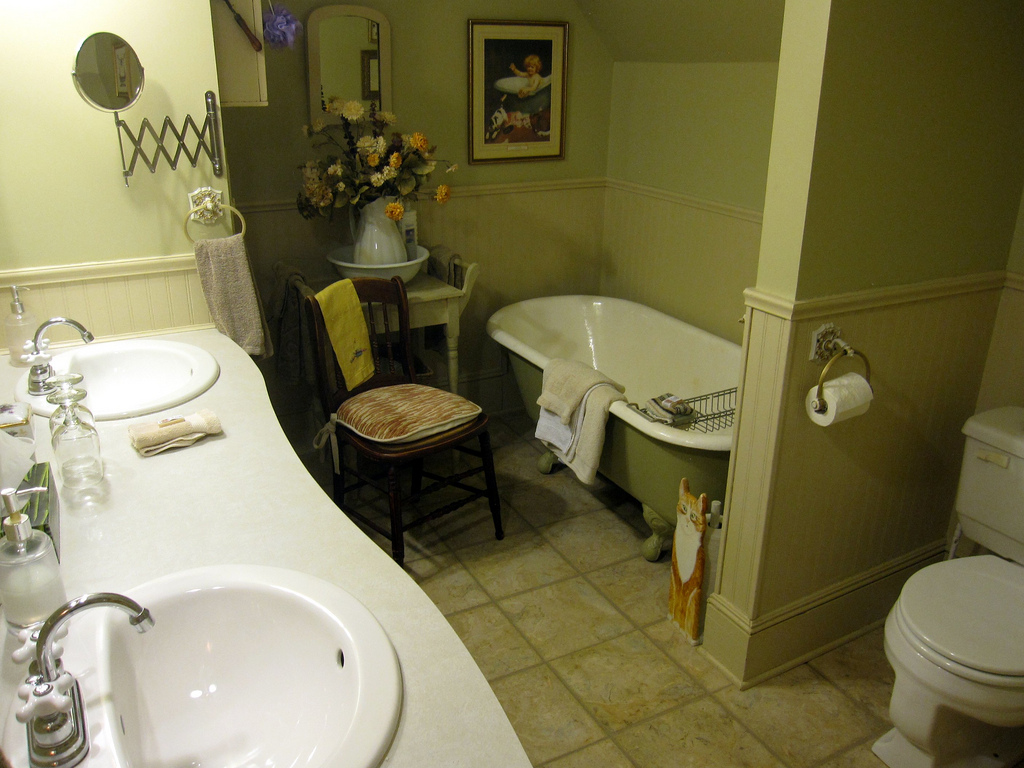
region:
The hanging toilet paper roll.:
[809, 329, 866, 459]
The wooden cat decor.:
[666, 484, 705, 634]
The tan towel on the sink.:
[120, 420, 234, 463]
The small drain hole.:
[329, 641, 358, 676]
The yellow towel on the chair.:
[319, 282, 376, 382]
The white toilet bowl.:
[878, 386, 1022, 761]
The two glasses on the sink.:
[49, 386, 101, 492]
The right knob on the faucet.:
[21, 680, 75, 726]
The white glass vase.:
[332, 195, 425, 278]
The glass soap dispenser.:
[6, 481, 63, 622]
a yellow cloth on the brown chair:
[324, 282, 379, 387]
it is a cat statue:
[640, 478, 729, 640]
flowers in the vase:
[294, 100, 435, 257]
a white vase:
[345, 192, 413, 284]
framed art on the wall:
[460, 12, 565, 164]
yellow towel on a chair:
[316, 275, 377, 389]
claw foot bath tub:
[490, 291, 735, 558]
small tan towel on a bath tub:
[532, 362, 619, 411]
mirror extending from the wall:
[68, 31, 223, 180]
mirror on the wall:
[297, 3, 397, 133]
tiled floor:
[318, 389, 1017, 764]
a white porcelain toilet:
[867, 407, 1022, 765]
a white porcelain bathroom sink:
[52, 560, 403, 766]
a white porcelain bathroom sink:
[24, 342, 215, 419]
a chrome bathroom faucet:
[16, 587, 152, 766]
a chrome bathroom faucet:
[21, 318, 92, 396]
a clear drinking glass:
[46, 394, 105, 493]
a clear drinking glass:
[46, 373, 94, 441]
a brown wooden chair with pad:
[305, 272, 505, 567]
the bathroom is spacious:
[55, 4, 871, 673]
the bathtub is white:
[573, 367, 751, 522]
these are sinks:
[93, 338, 315, 741]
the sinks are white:
[64, 329, 347, 764]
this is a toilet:
[877, 531, 1002, 686]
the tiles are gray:
[485, 552, 678, 739]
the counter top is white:
[143, 446, 344, 563]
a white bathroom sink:
[122, 554, 484, 764]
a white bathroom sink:
[61, 294, 224, 472]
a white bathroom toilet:
[857, 420, 1014, 709]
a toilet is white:
[807, 317, 1011, 729]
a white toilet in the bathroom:
[915, 455, 1017, 624]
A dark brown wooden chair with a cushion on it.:
[292, 285, 518, 561]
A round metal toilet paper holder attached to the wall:
[803, 339, 880, 434]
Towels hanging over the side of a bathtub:
[521, 335, 633, 488]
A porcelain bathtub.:
[478, 289, 754, 585]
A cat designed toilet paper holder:
[652, 488, 739, 635]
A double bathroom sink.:
[9, 305, 459, 765]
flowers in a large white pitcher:
[286, 83, 457, 286]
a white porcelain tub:
[489, 277, 734, 568]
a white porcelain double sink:
[13, 312, 544, 766]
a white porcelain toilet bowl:
[836, 399, 1018, 766]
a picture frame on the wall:
[461, 13, 570, 170]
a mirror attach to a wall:
[68, 26, 231, 182]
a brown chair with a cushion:
[296, 269, 512, 551]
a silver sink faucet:
[6, 582, 159, 766]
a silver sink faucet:
[13, 316, 109, 396]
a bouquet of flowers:
[296, 92, 455, 286]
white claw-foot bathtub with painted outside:
[479, 289, 752, 572]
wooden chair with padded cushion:
[304, 275, 510, 567]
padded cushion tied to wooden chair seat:
[301, 383, 489, 481]